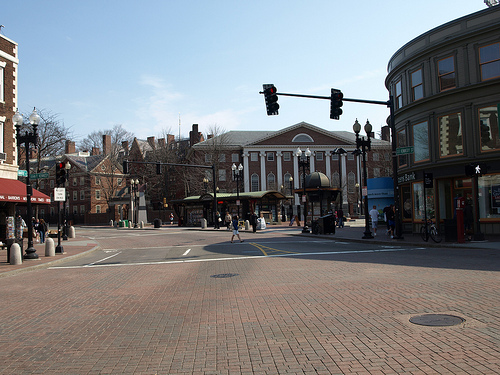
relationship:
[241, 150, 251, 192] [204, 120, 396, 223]
pillar on building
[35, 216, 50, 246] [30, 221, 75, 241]
person on sidewalk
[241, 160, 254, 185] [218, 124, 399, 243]
column on building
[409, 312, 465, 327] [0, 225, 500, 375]
cover on road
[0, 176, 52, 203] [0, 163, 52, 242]
awning on shop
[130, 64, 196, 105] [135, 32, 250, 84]
clouds in sky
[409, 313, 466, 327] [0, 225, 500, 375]
cover in road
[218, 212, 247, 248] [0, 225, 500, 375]
woman crossing road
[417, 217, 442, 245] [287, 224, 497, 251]
bike on sidewalk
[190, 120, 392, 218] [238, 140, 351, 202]
building with columns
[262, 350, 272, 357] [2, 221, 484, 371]
brick covering road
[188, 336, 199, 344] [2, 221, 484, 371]
brick covering road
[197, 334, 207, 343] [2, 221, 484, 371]
brick covering road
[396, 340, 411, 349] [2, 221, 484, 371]
brick covering road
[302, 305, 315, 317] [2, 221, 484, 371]
brick covering road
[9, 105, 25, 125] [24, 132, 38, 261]
street light attached to pole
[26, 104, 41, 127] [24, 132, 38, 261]
street light attached to pole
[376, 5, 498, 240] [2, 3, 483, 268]
building standing in background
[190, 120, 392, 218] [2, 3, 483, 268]
building standing in background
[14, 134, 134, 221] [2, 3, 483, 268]
building standing in background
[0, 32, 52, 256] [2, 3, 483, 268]
building standing in background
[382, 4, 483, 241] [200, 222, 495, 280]
building casting shadow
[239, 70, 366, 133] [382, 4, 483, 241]
light attached to building